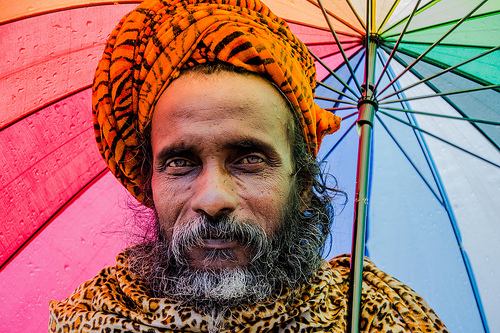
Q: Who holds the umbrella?
A: A man.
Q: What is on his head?
A: A cloth turban.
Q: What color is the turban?
A: Orange with black.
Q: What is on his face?
A: A full beard.